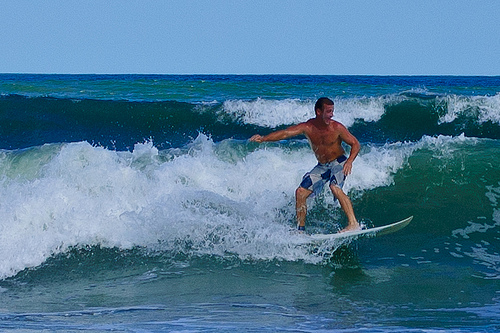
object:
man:
[248, 98, 362, 235]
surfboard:
[310, 215, 414, 241]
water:
[0, 72, 500, 333]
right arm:
[249, 123, 309, 143]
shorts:
[299, 152, 352, 191]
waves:
[0, 85, 500, 285]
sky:
[0, 1, 500, 78]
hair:
[315, 97, 335, 111]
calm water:
[1, 73, 499, 94]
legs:
[328, 169, 361, 236]